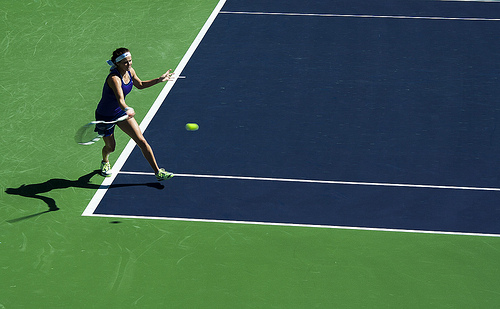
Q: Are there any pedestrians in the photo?
A: No, there are no pedestrians.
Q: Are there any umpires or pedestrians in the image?
A: No, there are no pedestrians or umpires.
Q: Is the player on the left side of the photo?
A: Yes, the player is on the left of the image.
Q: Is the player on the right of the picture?
A: No, the player is on the left of the image.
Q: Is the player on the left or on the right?
A: The player is on the left of the image.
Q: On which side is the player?
A: The player is on the left of the image.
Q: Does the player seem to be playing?
A: Yes, the player is playing.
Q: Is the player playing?
A: Yes, the player is playing.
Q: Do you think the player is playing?
A: Yes, the player is playing.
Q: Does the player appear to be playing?
A: Yes, the player is playing.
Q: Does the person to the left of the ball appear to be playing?
A: Yes, the player is playing.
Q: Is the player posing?
A: No, the player is playing.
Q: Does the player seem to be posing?
A: No, the player is playing.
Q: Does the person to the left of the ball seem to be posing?
A: No, the player is playing.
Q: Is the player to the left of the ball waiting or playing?
A: The player is playing.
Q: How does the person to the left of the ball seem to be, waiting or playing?
A: The player is playing.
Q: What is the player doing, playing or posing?
A: The player is playing.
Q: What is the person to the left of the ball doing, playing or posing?
A: The player is playing.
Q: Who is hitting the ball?
A: The player is hitting the ball.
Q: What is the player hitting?
A: The player is hitting the ball.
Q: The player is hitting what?
A: The player is hitting the ball.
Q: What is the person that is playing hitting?
A: The player is hitting the ball.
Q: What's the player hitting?
A: The player is hitting the ball.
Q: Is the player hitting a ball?
A: Yes, the player is hitting a ball.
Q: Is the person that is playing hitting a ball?
A: Yes, the player is hitting a ball.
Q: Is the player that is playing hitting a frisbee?
A: No, the player is hitting a ball.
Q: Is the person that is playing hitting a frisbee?
A: No, the player is hitting a ball.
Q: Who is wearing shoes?
A: The player is wearing shoes.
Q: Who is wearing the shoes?
A: The player is wearing shoes.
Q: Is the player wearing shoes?
A: Yes, the player is wearing shoes.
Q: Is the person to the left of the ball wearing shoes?
A: Yes, the player is wearing shoes.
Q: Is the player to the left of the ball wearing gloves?
A: No, the player is wearing shoes.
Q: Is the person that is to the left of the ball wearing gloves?
A: No, the player is wearing shoes.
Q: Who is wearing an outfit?
A: The player is wearing an outfit.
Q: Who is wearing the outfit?
A: The player is wearing an outfit.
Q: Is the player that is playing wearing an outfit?
A: Yes, the player is wearing an outfit.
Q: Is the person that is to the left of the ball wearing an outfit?
A: Yes, the player is wearing an outfit.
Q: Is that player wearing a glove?
A: No, the player is wearing an outfit.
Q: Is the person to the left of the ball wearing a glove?
A: No, the player is wearing an outfit.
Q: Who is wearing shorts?
A: The player is wearing shorts.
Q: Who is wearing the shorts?
A: The player is wearing shorts.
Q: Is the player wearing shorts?
A: Yes, the player is wearing shorts.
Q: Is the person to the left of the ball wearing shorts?
A: Yes, the player is wearing shorts.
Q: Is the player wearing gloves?
A: No, the player is wearing shorts.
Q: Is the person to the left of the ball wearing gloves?
A: No, the player is wearing shorts.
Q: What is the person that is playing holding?
A: The player is holding the tennis racket.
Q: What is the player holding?
A: The player is holding the tennis racket.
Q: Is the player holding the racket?
A: Yes, the player is holding the racket.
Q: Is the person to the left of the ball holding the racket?
A: Yes, the player is holding the racket.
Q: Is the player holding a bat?
A: No, the player is holding the racket.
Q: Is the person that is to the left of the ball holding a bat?
A: No, the player is holding the racket.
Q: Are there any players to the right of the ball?
A: No, the player is to the left of the ball.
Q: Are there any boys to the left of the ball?
A: No, there is a player to the left of the ball.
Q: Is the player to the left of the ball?
A: Yes, the player is to the left of the ball.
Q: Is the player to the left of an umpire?
A: No, the player is to the left of the ball.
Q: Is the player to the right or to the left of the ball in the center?
A: The player is to the left of the ball.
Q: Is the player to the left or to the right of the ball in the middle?
A: The player is to the left of the ball.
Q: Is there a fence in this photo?
A: No, there are no fences.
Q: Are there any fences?
A: No, there are no fences.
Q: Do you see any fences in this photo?
A: No, there are no fences.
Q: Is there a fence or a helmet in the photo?
A: No, there are no fences or helmets.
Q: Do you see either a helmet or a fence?
A: No, there are no fences or helmets.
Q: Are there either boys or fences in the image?
A: No, there are no fences or boys.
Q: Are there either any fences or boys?
A: No, there are no fences or boys.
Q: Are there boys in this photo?
A: No, there are no boys.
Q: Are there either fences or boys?
A: No, there are no boys or fences.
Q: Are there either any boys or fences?
A: No, there are no boys or fences.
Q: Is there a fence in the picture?
A: No, there are no fences.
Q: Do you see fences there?
A: No, there are no fences.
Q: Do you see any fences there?
A: No, there are no fences.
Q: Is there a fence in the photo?
A: No, there are no fences.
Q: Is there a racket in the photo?
A: Yes, there is a racket.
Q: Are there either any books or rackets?
A: Yes, there is a racket.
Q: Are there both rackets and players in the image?
A: Yes, there are both a racket and a player.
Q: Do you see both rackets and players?
A: Yes, there are both a racket and a player.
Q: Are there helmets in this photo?
A: No, there are no helmets.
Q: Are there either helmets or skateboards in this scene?
A: No, there are no helmets or skateboards.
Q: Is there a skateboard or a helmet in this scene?
A: No, there are no helmets or skateboards.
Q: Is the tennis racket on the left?
A: Yes, the tennis racket is on the left of the image.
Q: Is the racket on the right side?
A: No, the racket is on the left of the image.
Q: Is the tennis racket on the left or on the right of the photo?
A: The tennis racket is on the left of the image.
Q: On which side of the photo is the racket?
A: The racket is on the left of the image.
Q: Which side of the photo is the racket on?
A: The racket is on the left of the image.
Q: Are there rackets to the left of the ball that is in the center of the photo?
A: Yes, there is a racket to the left of the ball.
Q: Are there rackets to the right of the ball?
A: No, the racket is to the left of the ball.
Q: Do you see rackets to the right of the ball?
A: No, the racket is to the left of the ball.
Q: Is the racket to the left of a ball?
A: Yes, the racket is to the left of a ball.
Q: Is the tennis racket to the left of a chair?
A: No, the tennis racket is to the left of a ball.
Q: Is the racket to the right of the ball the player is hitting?
A: No, the racket is to the left of the ball.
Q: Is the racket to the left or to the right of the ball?
A: The racket is to the left of the ball.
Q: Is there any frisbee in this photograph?
A: No, there are no frisbees.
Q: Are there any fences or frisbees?
A: No, there are no frisbees or fences.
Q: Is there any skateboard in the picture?
A: No, there are no skateboards.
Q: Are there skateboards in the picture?
A: No, there are no skateboards.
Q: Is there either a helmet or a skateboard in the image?
A: No, there are no skateboards or helmets.